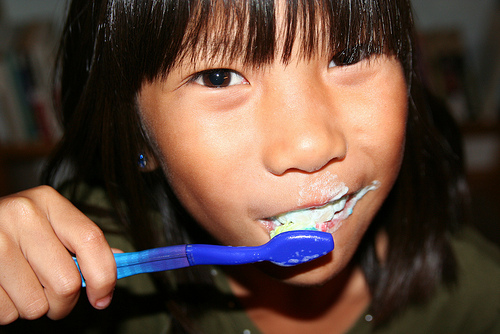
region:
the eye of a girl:
[179, 55, 263, 102]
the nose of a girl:
[261, 60, 350, 182]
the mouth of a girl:
[254, 172, 374, 240]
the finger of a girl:
[41, 181, 119, 314]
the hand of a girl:
[0, 173, 125, 332]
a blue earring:
[135, 148, 155, 171]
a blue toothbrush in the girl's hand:
[66, 205, 336, 305]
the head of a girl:
[123, 0, 419, 310]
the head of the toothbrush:
[266, 220, 339, 270]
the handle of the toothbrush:
[70, 235, 267, 294]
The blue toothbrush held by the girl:
[66, 221, 337, 290]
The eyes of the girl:
[170, 36, 389, 103]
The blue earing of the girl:
[133, 148, 153, 176]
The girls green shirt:
[39, 172, 499, 332]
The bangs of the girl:
[169, 1, 401, 64]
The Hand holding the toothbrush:
[0, 180, 129, 327]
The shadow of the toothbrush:
[79, 286, 259, 328]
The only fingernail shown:
[91, 285, 114, 316]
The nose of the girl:
[255, 56, 352, 179]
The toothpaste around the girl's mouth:
[254, 169, 379, 247]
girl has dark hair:
[23, 1, 305, 184]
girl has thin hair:
[100, 1, 287, 100]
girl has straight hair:
[42, 13, 301, 128]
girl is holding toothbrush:
[91, 200, 438, 293]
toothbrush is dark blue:
[27, 212, 296, 262]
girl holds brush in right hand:
[0, 168, 348, 329]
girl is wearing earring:
[103, 103, 171, 188]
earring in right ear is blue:
[124, 131, 165, 188]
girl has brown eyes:
[176, 62, 272, 127]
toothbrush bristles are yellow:
[261, 190, 400, 256]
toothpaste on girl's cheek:
[353, 170, 392, 204]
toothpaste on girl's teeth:
[282, 207, 339, 228]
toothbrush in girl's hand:
[99, 224, 338, 276]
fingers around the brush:
[58, 209, 113, 311]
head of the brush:
[256, 229, 338, 264]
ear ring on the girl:
[129, 138, 150, 175]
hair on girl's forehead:
[223, 42, 343, 89]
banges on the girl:
[98, 22, 413, 105]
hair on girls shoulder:
[365, 242, 472, 332]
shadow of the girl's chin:
[303, 288, 355, 327]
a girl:
[154, 54, 302, 272]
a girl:
[84, 25, 292, 326]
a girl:
[180, 115, 365, 325]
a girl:
[161, 140, 298, 317]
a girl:
[106, 87, 239, 274]